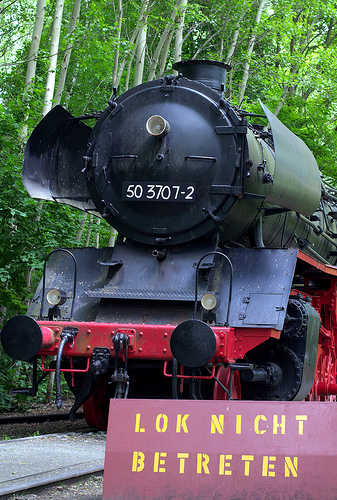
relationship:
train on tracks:
[15, 78, 332, 410] [6, 418, 123, 497]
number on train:
[120, 172, 205, 216] [15, 78, 332, 410]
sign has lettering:
[107, 399, 336, 497] [124, 411, 303, 478]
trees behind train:
[3, 9, 86, 408] [15, 78, 332, 410]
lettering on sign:
[124, 411, 303, 478] [107, 399, 336, 497]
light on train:
[132, 114, 183, 144] [15, 78, 332, 410]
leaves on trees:
[3, 93, 48, 123] [3, 9, 86, 408]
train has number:
[15, 78, 332, 410] [120, 172, 205, 216]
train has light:
[15, 78, 332, 410] [145, 114, 172, 135]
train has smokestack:
[15, 78, 332, 410] [175, 48, 248, 99]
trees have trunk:
[3, 9, 86, 408] [45, 4, 60, 113]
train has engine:
[15, 78, 332, 410] [233, 309, 336, 393]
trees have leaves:
[3, 9, 86, 408] [3, 93, 48, 123]